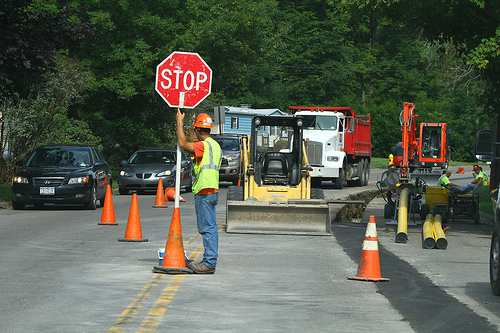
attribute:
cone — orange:
[342, 206, 391, 284]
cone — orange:
[148, 201, 202, 281]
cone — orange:
[121, 184, 146, 242]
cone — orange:
[117, 184, 151, 242]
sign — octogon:
[148, 44, 218, 113]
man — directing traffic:
[172, 104, 226, 276]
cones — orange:
[93, 170, 193, 277]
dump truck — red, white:
[288, 102, 373, 191]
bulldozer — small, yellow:
[222, 113, 333, 237]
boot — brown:
[186, 260, 216, 273]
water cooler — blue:
[155, 247, 187, 268]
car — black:
[9, 141, 115, 208]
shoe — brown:
[186, 260, 216, 275]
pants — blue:
[193, 191, 220, 270]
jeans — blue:
[192, 190, 221, 273]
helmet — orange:
[189, 111, 216, 130]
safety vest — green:
[189, 135, 225, 195]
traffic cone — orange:
[96, 182, 119, 224]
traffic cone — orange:
[116, 190, 150, 242]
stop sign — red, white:
[154, 50, 214, 109]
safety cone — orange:
[151, 205, 191, 274]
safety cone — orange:
[114, 189, 151, 244]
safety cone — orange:
[97, 182, 119, 227]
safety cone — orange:
[151, 174, 167, 208]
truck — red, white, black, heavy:
[286, 102, 374, 189]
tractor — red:
[374, 99, 448, 185]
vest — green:
[190, 136, 223, 193]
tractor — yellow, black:
[222, 109, 333, 240]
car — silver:
[116, 146, 193, 192]